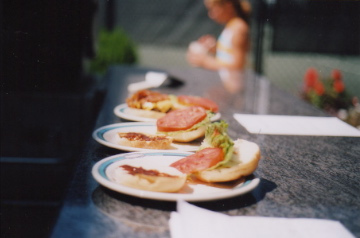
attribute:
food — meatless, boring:
[112, 88, 263, 193]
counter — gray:
[51, 68, 359, 236]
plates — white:
[90, 87, 262, 204]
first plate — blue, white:
[90, 149, 264, 203]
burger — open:
[109, 136, 262, 192]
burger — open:
[114, 108, 223, 148]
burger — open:
[126, 93, 218, 117]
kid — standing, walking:
[186, 0, 252, 72]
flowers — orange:
[300, 68, 354, 112]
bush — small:
[87, 26, 140, 79]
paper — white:
[231, 112, 359, 139]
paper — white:
[163, 197, 354, 237]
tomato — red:
[155, 105, 209, 132]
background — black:
[271, 1, 358, 56]